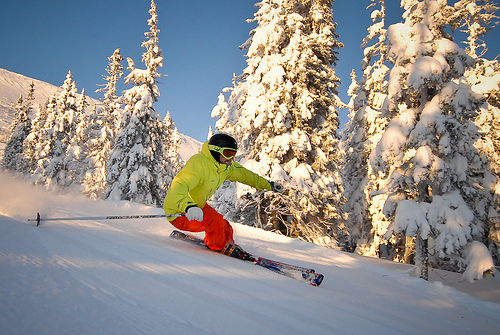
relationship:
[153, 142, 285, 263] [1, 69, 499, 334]
man on hill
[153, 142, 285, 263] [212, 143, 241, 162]
man wearing goggles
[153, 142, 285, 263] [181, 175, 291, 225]
man wearing gloves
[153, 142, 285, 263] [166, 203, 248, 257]
man wearing pants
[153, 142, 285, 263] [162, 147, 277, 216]
man wearing a jacket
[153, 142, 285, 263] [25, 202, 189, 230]
man has a ski pole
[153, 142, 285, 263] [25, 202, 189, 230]
man using a ski pole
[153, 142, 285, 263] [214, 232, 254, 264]
man wearing boots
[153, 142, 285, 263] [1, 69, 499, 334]
man skiing on a hill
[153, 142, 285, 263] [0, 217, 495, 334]
man in a shadow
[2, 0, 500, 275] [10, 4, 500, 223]
trees have snow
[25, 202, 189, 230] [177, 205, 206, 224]
ski pole in right hand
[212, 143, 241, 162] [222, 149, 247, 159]
goggles have lenses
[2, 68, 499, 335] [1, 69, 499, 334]
snow on hill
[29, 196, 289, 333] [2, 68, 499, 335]
tracks are in snow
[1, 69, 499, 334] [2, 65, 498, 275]
hill in background